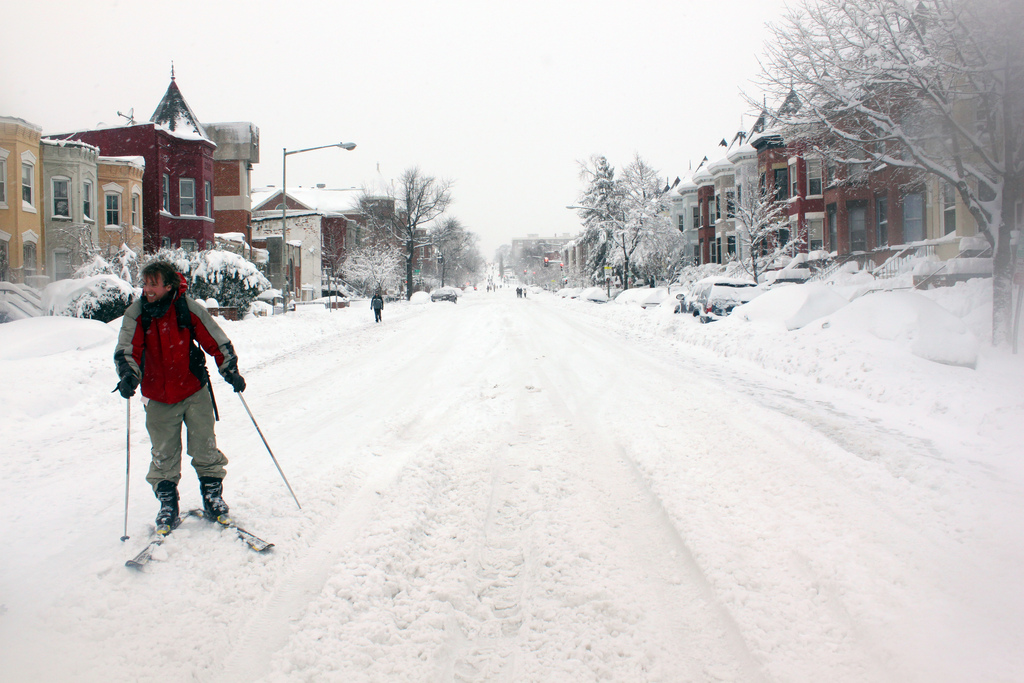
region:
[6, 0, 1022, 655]
a scene outside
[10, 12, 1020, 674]
a scene during the day time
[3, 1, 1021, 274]
a white sky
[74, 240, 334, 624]
a happy man skiing down the road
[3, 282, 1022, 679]
snow is on the ground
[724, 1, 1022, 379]
a tree with no leaves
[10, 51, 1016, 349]
rows of buildings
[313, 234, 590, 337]
people in background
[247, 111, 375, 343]
street light pole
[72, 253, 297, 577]
person skiing on the snow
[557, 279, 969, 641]
tire tracks in the snow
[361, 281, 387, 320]
person walking on the snow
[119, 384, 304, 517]
ski poles the man is holding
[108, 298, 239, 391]
red and gray jacket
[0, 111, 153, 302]
gray building between two yellow buildings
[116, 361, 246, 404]
black gloves the man is wearing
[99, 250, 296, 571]
a man on skis in the snow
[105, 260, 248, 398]
a man in a red and grey coat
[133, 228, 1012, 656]
a snow covered city street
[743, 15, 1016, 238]
snow on tree branches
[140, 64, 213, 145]
snow on the roof of a house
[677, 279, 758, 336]
a vehicle covered in snow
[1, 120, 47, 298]
the tan exterior of a building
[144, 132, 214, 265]
the red exterior of a building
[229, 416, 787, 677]
tire tracks in the snow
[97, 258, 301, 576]
A man on a pair of skis.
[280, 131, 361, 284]
A silver street light .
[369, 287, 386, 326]
A person walking in the snow.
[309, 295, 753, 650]
A snow covered street.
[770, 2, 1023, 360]
A tree with no leaves.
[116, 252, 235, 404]
A man wearing a red jacket.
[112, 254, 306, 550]
A man with ski poles.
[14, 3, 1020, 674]
a street with houses on both sides.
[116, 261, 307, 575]
A man cross country skiing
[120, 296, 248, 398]
Black and gray coat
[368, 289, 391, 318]
A woman walking down the street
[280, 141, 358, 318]
A street light to light the street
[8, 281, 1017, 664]
A street covered in snow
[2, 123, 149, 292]
Row of three town houses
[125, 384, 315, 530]
Gray skis for cross country skiing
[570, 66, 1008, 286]
A long row of town houses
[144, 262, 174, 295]
head of a man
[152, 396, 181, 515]
leg of a man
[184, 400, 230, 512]
leg of a man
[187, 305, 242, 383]
arm of a man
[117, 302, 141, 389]
arm of a man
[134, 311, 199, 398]
the shirt is red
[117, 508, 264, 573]
the skis are gray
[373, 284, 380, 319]
person in the snow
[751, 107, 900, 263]
the paint is red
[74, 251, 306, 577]
Man in red coat and skis.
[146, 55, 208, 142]
Roof peak on building.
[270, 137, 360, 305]
Street light over the roadway.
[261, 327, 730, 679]
Tracks through the snow.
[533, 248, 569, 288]
Stoplight over the street.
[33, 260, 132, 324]
Snow covered bush in front of house.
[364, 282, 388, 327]
Person in a blue and black coat and black pants.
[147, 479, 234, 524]
Pair of black snow boots.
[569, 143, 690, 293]
Snow covered trees along the street.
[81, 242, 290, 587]
a man on skis